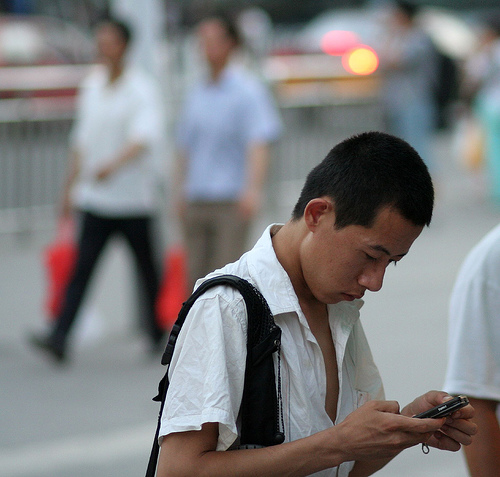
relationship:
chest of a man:
[291, 295, 348, 432] [148, 137, 445, 474]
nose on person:
[361, 266, 387, 296] [150, 129, 477, 474]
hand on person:
[333, 392, 440, 466] [150, 129, 477, 474]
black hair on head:
[288, 125, 438, 233] [290, 125, 435, 305]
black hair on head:
[93, 15, 131, 51] [86, 13, 134, 65]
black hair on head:
[197, 11, 242, 46] [190, 11, 242, 68]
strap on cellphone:
[418, 440, 428, 452] [409, 394, 469, 425]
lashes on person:
[391, 257, 399, 264] [150, 129, 477, 474]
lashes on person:
[364, 255, 377, 260] [150, 129, 477, 474]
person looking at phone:
[150, 129, 477, 474] [421, 395, 466, 417]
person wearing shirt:
[150, 129, 477, 474] [156, 220, 389, 475]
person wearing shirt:
[174, 9, 324, 284] [176, 63, 294, 207]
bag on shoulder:
[162, 276, 289, 472] [135, 239, 321, 417]